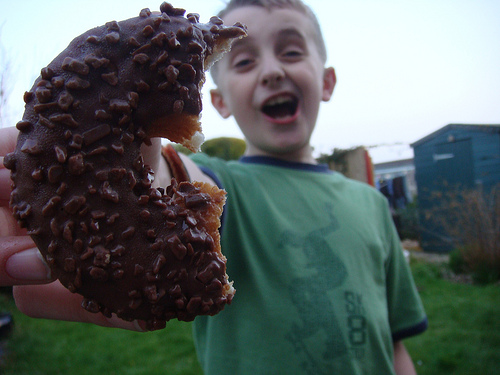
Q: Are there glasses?
A: No, there are no glasses.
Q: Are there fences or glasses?
A: No, there are no glasses or fences.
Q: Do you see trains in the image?
A: No, there are no trains.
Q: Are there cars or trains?
A: No, there are no trains or cars.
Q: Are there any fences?
A: No, there are no fences.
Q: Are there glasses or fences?
A: No, there are no fences or glasses.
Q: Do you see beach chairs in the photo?
A: No, there are no beach chairs.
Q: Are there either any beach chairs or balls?
A: No, there are no beach chairs or balls.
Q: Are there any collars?
A: Yes, there is a collar.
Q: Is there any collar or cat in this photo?
A: Yes, there is a collar.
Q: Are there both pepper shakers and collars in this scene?
A: No, there is a collar but no pepper shakers.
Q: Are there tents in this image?
A: No, there are no tents.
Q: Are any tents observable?
A: No, there are no tents.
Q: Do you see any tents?
A: No, there are no tents.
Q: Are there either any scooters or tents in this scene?
A: No, there are no tents or scooters.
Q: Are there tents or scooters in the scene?
A: No, there are no tents or scooters.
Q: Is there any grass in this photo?
A: Yes, there is grass.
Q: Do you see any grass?
A: Yes, there is grass.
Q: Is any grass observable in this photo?
A: Yes, there is grass.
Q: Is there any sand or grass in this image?
A: Yes, there is grass.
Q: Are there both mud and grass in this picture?
A: No, there is grass but no mud.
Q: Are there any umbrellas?
A: No, there are no umbrellas.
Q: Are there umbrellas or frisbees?
A: No, there are no umbrellas or frisbees.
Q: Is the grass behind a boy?
A: Yes, the grass is behind a boy.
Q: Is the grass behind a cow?
A: No, the grass is behind a boy.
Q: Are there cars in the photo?
A: No, there are no cars.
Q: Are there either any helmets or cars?
A: No, there are no cars or helmets.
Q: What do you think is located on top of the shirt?
A: The number is on top of the shirt.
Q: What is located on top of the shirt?
A: The number is on top of the shirt.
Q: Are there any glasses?
A: No, there are no glasses.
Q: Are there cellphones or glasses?
A: No, there are no glasses or cellphones.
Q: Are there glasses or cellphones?
A: No, there are no glasses or cellphones.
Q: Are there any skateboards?
A: No, there are no skateboards.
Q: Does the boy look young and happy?
A: Yes, the boy is young and happy.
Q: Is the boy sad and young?
A: No, the boy is young but happy.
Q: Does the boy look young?
A: Yes, the boy is young.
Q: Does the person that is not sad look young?
A: Yes, the boy is young.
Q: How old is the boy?
A: The boy is young.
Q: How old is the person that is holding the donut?
A: The boy is young.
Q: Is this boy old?
A: No, the boy is young.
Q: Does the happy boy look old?
A: No, the boy is young.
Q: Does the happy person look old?
A: No, the boy is young.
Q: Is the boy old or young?
A: The boy is young.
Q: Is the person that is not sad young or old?
A: The boy is young.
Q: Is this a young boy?
A: Yes, this is a young boy.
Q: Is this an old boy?
A: No, this is a young boy.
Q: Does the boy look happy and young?
A: Yes, the boy is happy and young.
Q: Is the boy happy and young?
A: Yes, the boy is happy and young.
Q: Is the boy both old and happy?
A: No, the boy is happy but young.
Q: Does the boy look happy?
A: Yes, the boy is happy.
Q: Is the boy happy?
A: Yes, the boy is happy.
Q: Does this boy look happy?
A: Yes, the boy is happy.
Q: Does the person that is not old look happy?
A: Yes, the boy is happy.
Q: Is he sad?
A: No, the boy is happy.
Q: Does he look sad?
A: No, the boy is happy.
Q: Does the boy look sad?
A: No, the boy is happy.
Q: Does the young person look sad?
A: No, the boy is happy.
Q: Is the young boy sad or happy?
A: The boy is happy.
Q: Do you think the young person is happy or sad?
A: The boy is happy.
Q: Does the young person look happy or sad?
A: The boy is happy.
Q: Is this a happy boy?
A: Yes, this is a happy boy.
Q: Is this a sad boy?
A: No, this is a happy boy.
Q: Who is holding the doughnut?
A: The boy is holding the doughnut.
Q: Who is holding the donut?
A: The boy is holding the doughnut.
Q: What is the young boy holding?
A: The boy is holding the doughnut.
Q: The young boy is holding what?
A: The boy is holding the doughnut.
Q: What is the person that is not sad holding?
A: The boy is holding the doughnut.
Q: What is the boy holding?
A: The boy is holding the doughnut.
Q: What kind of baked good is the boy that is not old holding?
A: The boy is holding the doughnut.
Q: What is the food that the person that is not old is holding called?
A: The food is a donut.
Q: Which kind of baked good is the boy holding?
A: The boy is holding the doughnut.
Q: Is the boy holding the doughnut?
A: Yes, the boy is holding the doughnut.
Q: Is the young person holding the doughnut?
A: Yes, the boy is holding the doughnut.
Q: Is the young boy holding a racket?
A: No, the boy is holding the doughnut.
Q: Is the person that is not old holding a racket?
A: No, the boy is holding the doughnut.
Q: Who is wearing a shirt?
A: The boy is wearing a shirt.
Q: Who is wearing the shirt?
A: The boy is wearing a shirt.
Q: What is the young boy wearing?
A: The boy is wearing a shirt.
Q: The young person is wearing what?
A: The boy is wearing a shirt.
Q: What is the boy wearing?
A: The boy is wearing a shirt.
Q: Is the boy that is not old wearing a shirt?
A: Yes, the boy is wearing a shirt.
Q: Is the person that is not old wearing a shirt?
A: Yes, the boy is wearing a shirt.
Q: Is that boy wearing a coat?
A: No, the boy is wearing a shirt.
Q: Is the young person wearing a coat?
A: No, the boy is wearing a shirt.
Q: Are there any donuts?
A: Yes, there is a donut.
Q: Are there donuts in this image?
A: Yes, there is a donut.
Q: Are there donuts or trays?
A: Yes, there is a donut.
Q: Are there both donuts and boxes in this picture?
A: No, there is a donut but no boxes.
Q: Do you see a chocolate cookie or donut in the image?
A: Yes, there is a chocolate donut.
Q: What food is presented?
A: The food is a donut.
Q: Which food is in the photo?
A: The food is a donut.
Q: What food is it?
A: The food is a donut.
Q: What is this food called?
A: This is a donut.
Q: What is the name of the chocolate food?
A: The food is a donut.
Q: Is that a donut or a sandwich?
A: That is a donut.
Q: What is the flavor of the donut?
A: This is a chocolate donut.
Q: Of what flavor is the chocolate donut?
A: This is a chocolate donut.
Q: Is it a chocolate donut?
A: Yes, this is a chocolate donut.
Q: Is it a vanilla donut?
A: No, this is a chocolate donut.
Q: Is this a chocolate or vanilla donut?
A: This is a chocolate donut.